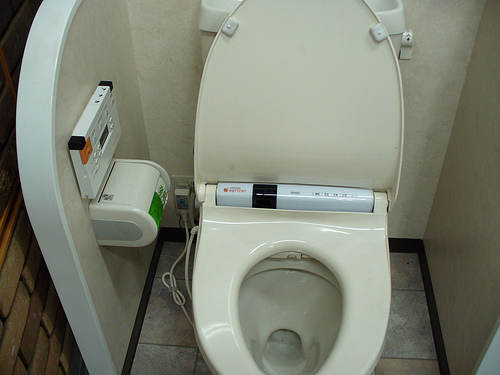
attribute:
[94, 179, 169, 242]
dispenser — tan, white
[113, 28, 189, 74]
wall — brick, brown, smooth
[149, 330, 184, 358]
floor — tiled, tile, beige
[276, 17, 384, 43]
lid — plastic, white, clean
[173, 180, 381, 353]
toilet — small, clean, connected, cream, dirty, tan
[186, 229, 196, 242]
gadget — plugged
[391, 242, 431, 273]
baseboard — black, wooden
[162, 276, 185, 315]
wire — white, plugged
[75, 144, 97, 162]
label — orange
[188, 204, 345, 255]
seat — white, tan